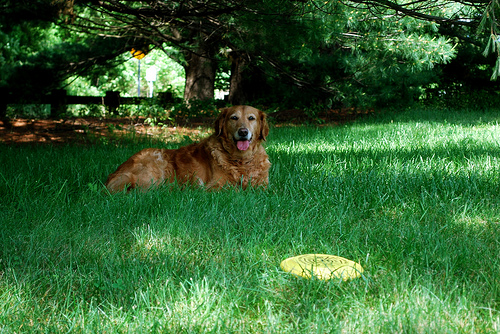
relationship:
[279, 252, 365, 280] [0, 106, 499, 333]
frisbee on grass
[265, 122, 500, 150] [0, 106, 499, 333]
spot on grass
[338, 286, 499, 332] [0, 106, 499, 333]
spot on grass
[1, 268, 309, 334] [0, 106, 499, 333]
spot on grass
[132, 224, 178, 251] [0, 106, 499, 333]
spot on grass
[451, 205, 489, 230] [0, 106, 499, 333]
spot on grass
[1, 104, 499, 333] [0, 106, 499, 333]
blade of grass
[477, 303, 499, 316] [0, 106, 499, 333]
blade of grass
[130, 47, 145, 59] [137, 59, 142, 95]
road sign on post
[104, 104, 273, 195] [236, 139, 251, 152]
dog has tongue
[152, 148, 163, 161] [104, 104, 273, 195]
spot on dog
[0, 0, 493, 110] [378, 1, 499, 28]
tree has branch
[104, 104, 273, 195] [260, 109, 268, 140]
dog has ear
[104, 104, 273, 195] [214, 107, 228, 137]
dog has ear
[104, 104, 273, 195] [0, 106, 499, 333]
dog laying in grass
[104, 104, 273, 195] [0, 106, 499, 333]
dog lying in grass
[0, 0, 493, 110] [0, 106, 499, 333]
tree behind grass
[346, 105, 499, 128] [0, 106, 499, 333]
shadow on grass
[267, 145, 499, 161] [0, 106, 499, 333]
shadow on grass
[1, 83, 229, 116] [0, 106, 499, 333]
fence behind grass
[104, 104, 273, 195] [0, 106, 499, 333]
dog sits on grass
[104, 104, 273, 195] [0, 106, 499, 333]
dog on grass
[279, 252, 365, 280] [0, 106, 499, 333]
frisbee in grass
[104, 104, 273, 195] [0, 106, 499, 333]
dog in grass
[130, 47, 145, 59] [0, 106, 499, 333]
road sign behind grass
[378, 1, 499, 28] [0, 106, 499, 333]
branch above grass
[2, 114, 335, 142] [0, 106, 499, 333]
dirt beyond grass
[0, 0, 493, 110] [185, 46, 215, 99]
tree has trunk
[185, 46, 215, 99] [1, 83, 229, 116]
trunk in front of fence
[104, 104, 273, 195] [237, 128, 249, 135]
dog has nose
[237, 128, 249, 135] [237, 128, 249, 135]
nose on nose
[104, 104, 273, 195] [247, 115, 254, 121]
dog has eye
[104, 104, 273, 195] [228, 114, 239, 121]
dog has eye